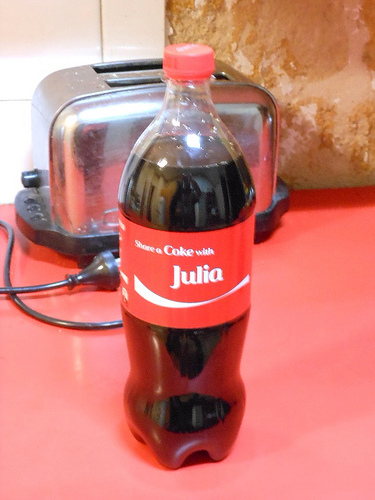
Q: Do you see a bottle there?
A: Yes, there is a bottle.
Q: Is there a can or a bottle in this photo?
A: Yes, there is a bottle.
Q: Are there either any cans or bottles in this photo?
A: Yes, there is a bottle.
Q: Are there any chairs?
A: No, there are no chairs.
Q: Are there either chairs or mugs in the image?
A: No, there are no chairs or mugs.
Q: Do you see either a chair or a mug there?
A: No, there are no chairs or mugs.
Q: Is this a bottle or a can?
A: This is a bottle.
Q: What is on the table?
A: The bottle is on the table.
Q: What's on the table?
A: The bottle is on the table.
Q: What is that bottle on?
A: The bottle is on the table.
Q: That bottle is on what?
A: The bottle is on the table.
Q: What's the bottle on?
A: The bottle is on the table.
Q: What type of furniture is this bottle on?
A: The bottle is on the table.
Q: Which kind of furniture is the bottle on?
A: The bottle is on the table.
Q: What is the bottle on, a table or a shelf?
A: The bottle is on a table.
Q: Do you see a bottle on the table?
A: Yes, there is a bottle on the table.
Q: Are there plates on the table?
A: No, there is a bottle on the table.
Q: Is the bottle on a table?
A: Yes, the bottle is on a table.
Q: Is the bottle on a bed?
A: No, the bottle is on a table.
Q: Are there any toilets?
A: No, there are no toilets.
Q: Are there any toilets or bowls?
A: No, there are no toilets or bowls.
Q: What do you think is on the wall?
A: The tiles are on the wall.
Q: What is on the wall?
A: The tiles are on the wall.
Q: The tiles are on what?
A: The tiles are on the wall.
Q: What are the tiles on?
A: The tiles are on the wall.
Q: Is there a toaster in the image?
A: Yes, there is a toaster.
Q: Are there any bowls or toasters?
A: Yes, there is a toaster.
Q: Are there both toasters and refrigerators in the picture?
A: No, there is a toaster but no refrigerators.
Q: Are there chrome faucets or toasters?
A: Yes, there is a chrome toaster.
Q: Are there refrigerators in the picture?
A: No, there are no refrigerators.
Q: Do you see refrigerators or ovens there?
A: No, there are no refrigerators or ovens.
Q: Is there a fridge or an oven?
A: No, there are no refrigerators or ovens.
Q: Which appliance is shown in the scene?
A: The appliance is a toaster.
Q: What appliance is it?
A: The appliance is a toaster.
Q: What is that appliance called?
A: That is a toaster.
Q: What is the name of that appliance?
A: That is a toaster.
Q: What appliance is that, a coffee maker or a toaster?
A: That is a toaster.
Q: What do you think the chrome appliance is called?
A: The appliance is a toaster.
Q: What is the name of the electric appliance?
A: The appliance is a toaster.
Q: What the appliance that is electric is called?
A: The appliance is a toaster.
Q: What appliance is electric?
A: The appliance is a toaster.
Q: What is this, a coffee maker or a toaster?
A: This is a toaster.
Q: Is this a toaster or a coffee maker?
A: This is a toaster.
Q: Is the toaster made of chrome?
A: Yes, the toaster is made of chrome.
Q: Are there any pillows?
A: No, there are no pillows.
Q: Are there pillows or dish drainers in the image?
A: No, there are no pillows or dish drainers.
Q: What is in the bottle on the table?
A: The liquid is in the bottle.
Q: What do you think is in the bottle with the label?
A: The liquid is in the bottle.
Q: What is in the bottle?
A: The liquid is in the bottle.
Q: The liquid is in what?
A: The liquid is in the bottle.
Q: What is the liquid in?
A: The liquid is in the bottle.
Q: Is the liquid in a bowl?
A: No, the liquid is in a bottle.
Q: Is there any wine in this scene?
A: No, there is no wine.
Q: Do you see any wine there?
A: No, there is no wine.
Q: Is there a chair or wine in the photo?
A: No, there are no wine or chairs.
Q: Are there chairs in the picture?
A: No, there are no chairs.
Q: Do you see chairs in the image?
A: No, there are no chairs.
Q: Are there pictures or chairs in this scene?
A: No, there are no chairs or pictures.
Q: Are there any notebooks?
A: No, there are no notebooks.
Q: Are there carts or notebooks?
A: No, there are no notebooks or carts.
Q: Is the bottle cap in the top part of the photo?
A: Yes, the bottle cap is in the top of the image.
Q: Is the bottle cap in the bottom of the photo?
A: No, the bottle cap is in the top of the image.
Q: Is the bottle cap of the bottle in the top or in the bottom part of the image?
A: The bottle cap is in the top of the image.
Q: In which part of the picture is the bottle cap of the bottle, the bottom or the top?
A: The bottle cap is in the top of the image.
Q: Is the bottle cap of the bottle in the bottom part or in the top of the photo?
A: The bottle cap is in the top of the image.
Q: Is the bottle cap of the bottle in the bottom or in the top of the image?
A: The bottle cap is in the top of the image.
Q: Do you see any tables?
A: Yes, there is a table.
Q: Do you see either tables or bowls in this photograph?
A: Yes, there is a table.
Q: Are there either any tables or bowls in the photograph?
A: Yes, there is a table.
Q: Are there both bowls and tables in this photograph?
A: No, there is a table but no bowls.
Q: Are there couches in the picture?
A: No, there are no couches.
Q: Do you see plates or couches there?
A: No, there are no couches or plates.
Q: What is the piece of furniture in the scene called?
A: The piece of furniture is a table.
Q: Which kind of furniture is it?
A: The piece of furniture is a table.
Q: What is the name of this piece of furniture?
A: This is a table.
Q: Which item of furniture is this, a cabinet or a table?
A: This is a table.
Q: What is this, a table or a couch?
A: This is a table.